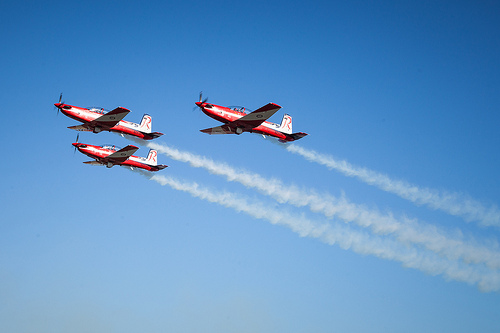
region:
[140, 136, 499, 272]
Smoke trail from the middle plane.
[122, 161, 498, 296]
Smoke trail from the bottom most plane.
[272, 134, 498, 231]
Smoke coming out of the top most plane.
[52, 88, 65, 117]
Furthest propeller to the left.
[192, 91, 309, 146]
Small plane that is furthest back.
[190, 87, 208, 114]
Propeller on the furthest back plane.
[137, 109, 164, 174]
Very tail end of two planes on top of each other.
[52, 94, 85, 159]
Propellers on the first two planes.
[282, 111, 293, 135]
Tail end of a red and white plane.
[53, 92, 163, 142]
Red and white plane that is furthest to the left.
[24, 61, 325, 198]
three planes in the sky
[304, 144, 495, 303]
smoke from the three planes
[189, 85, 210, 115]
propeller of a plane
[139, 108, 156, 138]
tail of a plane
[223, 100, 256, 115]
pilot of a plane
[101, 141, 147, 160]
left wing of a plane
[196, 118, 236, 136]
right wing of a plane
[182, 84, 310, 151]
one plane in the sky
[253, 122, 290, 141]
bottom of a plane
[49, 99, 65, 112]
nose of a plane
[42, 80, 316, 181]
three planes in flight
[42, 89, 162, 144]
middle plane in formation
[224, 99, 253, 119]
glass cover over cockpit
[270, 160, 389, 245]
three lines of exhaust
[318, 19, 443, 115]
clear blue daytime sky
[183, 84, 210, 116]
propeller on front of plane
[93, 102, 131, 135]
wing on side of plane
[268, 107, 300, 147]
white tail with red design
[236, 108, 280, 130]
bottom of plane wing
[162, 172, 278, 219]
trail of smoke behind plane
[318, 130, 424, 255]
white smoke from planes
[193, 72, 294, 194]
red and white plane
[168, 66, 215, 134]
proppeler on front of plane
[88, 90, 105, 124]
pilot in a plane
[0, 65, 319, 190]
three planes flying overhead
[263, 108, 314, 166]
tail of a plane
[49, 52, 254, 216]
three pilots in planes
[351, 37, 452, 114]
blue patch of sky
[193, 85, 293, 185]
plane flying thru air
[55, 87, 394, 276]
three planes with white smoke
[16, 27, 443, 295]
Three planes flying in formation.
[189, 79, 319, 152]
A red airplane on the right.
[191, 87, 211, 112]
Single engine on airplane on the right.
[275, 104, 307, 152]
Tail of airplane on the right.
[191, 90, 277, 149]
Wings of an airplane on the right.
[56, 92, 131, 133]
Wings of an airplane in the middle.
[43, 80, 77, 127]
Single engine of an airplane in the middle.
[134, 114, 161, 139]
Tail of an airplane in the middle.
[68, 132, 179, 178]
Red airplane on left side.